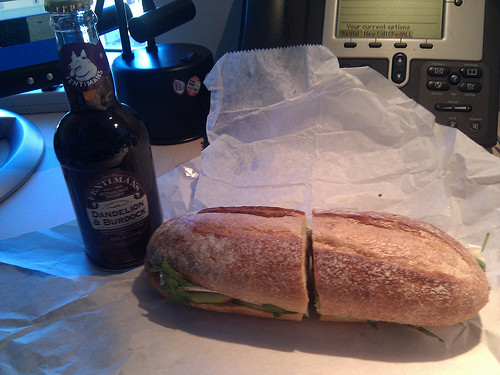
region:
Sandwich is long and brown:
[150, 195, 494, 332]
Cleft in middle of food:
[296, 190, 327, 333]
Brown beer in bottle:
[48, 20, 166, 262]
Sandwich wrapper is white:
[202, 59, 471, 230]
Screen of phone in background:
[333, 2, 443, 45]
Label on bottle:
[81, 171, 161, 237]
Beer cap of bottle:
[42, 2, 95, 12]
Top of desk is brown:
[5, 104, 107, 233]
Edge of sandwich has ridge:
[314, 206, 411, 232]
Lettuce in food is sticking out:
[146, 262, 197, 302]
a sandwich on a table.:
[107, 174, 498, 353]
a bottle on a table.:
[37, 0, 197, 263]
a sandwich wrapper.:
[198, 16, 498, 353]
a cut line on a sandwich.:
[259, 170, 330, 340]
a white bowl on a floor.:
[0, 96, 52, 195]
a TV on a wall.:
[317, 0, 492, 60]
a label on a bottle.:
[74, 144, 154, 264]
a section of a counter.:
[9, 190, 98, 296]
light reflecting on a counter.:
[170, 141, 212, 181]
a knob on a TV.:
[414, 30, 446, 68]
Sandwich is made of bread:
[137, 199, 494, 331]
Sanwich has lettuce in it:
[138, 199, 495, 345]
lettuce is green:
[137, 249, 202, 314]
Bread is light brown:
[138, 200, 493, 332]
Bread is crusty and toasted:
[138, 201, 495, 331]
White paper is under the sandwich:
[1, 38, 498, 373]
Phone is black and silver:
[209, 0, 498, 150]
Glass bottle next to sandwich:
[37, 0, 168, 275]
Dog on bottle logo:
[63, 47, 101, 86]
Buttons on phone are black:
[213, 0, 498, 152]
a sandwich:
[228, 166, 375, 364]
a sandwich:
[275, 163, 363, 322]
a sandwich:
[254, 180, 315, 295]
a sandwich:
[256, 205, 343, 363]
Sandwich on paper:
[146, 182, 496, 327]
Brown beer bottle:
[46, 0, 164, 251]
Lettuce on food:
[153, 252, 210, 312]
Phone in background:
[238, 11, 494, 135]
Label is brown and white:
[81, 166, 158, 236]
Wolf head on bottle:
[54, 39, 125, 95]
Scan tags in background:
[168, 77, 205, 97]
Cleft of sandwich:
[292, 202, 322, 318]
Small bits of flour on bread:
[201, 235, 232, 265]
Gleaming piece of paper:
[179, 160, 203, 186]